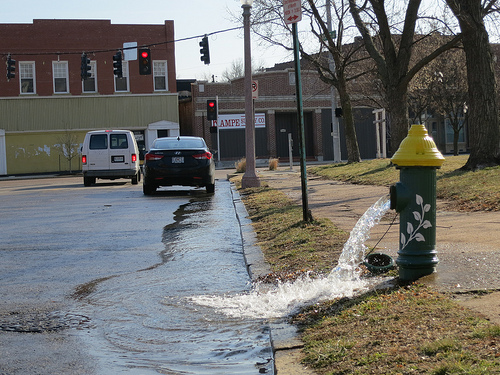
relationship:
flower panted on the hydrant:
[398, 191, 432, 258] [383, 108, 443, 281]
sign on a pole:
[283, 4, 302, 23] [289, 25, 312, 213]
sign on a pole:
[252, 80, 261, 99] [251, 100, 258, 167]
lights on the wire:
[200, 36, 210, 66] [10, 20, 273, 69]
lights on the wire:
[136, 45, 152, 73] [10, 20, 273, 69]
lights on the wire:
[109, 48, 126, 79] [10, 20, 273, 69]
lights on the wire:
[80, 60, 92, 82] [10, 20, 273, 69]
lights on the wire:
[2, 56, 22, 82] [10, 20, 273, 69]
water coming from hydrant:
[217, 193, 387, 318] [383, 108, 443, 281]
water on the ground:
[217, 232, 387, 318] [244, 169, 444, 359]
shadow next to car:
[92, 195, 114, 223] [134, 132, 220, 194]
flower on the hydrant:
[398, 191, 432, 258] [384, 117, 447, 274]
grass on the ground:
[239, 177, 467, 348] [242, 167, 462, 341]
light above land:
[132, 46, 156, 78] [24, 141, 447, 311]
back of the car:
[135, 132, 215, 192] [134, 132, 220, 194]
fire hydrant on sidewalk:
[387, 119, 445, 279] [269, 169, 469, 297]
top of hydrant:
[387, 124, 447, 167] [384, 117, 447, 274]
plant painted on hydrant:
[395, 190, 432, 256] [384, 117, 447, 274]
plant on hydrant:
[395, 190, 432, 256] [385, 120, 441, 268]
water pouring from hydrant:
[217, 193, 387, 318] [384, 117, 447, 274]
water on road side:
[217, 232, 387, 318] [179, 186, 255, 354]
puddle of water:
[107, 212, 272, 353] [217, 232, 387, 318]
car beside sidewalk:
[136, 132, 214, 192] [262, 115, 452, 295]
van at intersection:
[81, 127, 141, 185] [17, 147, 258, 195]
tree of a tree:
[365, 9, 431, 153] [335, 9, 443, 151]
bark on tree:
[459, 22, 499, 159] [429, 0, 499, 165]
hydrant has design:
[384, 117, 447, 274] [398, 189, 431, 249]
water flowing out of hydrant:
[217, 232, 387, 318] [384, 117, 447, 274]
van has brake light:
[81, 127, 141, 185] [127, 152, 136, 162]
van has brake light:
[81, 127, 141, 185] [80, 153, 88, 165]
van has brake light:
[81, 127, 141, 185] [104, 125, 113, 133]